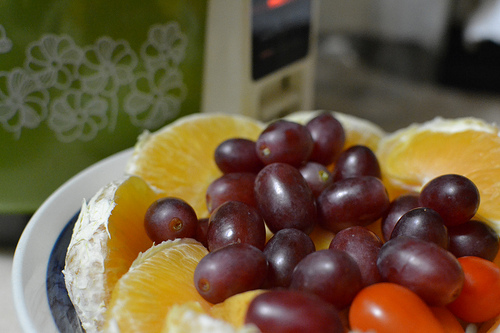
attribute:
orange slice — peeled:
[62, 177, 172, 332]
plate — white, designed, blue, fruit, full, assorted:
[13, 140, 151, 331]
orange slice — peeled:
[103, 238, 210, 331]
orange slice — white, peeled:
[132, 113, 267, 218]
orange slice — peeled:
[270, 110, 385, 176]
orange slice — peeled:
[375, 113, 499, 234]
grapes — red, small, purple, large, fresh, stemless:
[143, 111, 498, 332]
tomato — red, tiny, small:
[349, 282, 442, 332]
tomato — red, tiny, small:
[448, 255, 500, 317]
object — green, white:
[0, 1, 211, 247]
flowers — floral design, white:
[0, 21, 190, 144]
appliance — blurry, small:
[199, 0, 319, 128]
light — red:
[267, 0, 289, 8]